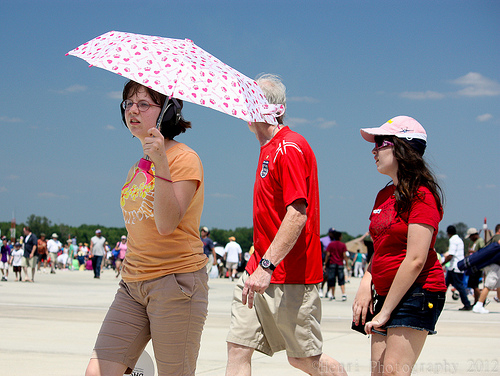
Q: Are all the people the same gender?
A: No, they are both male and female.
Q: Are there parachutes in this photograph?
A: No, there are no parachutes.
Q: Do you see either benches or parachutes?
A: No, there are no parachutes or benches.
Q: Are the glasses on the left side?
A: Yes, the glasses are on the left of the image.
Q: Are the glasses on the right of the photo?
A: No, the glasses are on the left of the image.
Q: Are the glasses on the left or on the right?
A: The glasses are on the left of the image.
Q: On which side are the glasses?
A: The glasses are on the left of the image.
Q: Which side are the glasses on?
A: The glasses are on the left of the image.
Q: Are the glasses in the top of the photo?
A: Yes, the glasses are in the top of the image.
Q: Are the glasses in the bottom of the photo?
A: No, the glasses are in the top of the image.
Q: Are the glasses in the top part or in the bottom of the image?
A: The glasses are in the top of the image.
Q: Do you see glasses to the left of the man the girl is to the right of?
A: Yes, there are glasses to the left of the man.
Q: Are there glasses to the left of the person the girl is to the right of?
A: Yes, there are glasses to the left of the man.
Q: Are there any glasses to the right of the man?
A: No, the glasses are to the left of the man.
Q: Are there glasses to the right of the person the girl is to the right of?
A: No, the glasses are to the left of the man.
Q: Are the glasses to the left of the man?
A: Yes, the glasses are to the left of the man.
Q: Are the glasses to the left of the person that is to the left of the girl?
A: Yes, the glasses are to the left of the man.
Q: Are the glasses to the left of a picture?
A: No, the glasses are to the left of the man.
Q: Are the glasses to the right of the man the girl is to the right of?
A: No, the glasses are to the left of the man.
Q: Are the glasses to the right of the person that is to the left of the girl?
A: No, the glasses are to the left of the man.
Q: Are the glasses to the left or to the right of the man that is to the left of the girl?
A: The glasses are to the left of the man.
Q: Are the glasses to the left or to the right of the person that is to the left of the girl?
A: The glasses are to the left of the man.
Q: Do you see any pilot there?
A: No, there are no pilots.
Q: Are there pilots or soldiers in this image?
A: No, there are no pilots or soldiers.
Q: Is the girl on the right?
A: Yes, the girl is on the right of the image.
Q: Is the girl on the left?
A: No, the girl is on the right of the image.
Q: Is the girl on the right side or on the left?
A: The girl is on the right of the image.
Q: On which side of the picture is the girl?
A: The girl is on the right of the image.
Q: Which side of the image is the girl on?
A: The girl is on the right of the image.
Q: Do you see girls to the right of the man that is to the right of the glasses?
A: Yes, there is a girl to the right of the man.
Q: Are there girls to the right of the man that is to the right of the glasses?
A: Yes, there is a girl to the right of the man.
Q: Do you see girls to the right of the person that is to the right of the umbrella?
A: Yes, there is a girl to the right of the man.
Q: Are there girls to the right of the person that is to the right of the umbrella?
A: Yes, there is a girl to the right of the man.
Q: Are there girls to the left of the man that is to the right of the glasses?
A: No, the girl is to the right of the man.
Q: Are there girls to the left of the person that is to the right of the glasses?
A: No, the girl is to the right of the man.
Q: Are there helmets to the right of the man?
A: No, there is a girl to the right of the man.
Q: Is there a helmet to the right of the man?
A: No, there is a girl to the right of the man.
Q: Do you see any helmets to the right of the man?
A: No, there is a girl to the right of the man.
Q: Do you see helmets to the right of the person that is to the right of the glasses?
A: No, there is a girl to the right of the man.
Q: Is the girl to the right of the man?
A: Yes, the girl is to the right of the man.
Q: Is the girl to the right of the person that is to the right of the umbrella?
A: Yes, the girl is to the right of the man.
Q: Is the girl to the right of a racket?
A: No, the girl is to the right of the man.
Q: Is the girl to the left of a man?
A: No, the girl is to the right of a man.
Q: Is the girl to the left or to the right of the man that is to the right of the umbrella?
A: The girl is to the right of the man.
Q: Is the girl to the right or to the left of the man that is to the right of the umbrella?
A: The girl is to the right of the man.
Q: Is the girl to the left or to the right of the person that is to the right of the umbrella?
A: The girl is to the right of the man.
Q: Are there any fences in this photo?
A: No, there are no fences.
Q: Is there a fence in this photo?
A: No, there are no fences.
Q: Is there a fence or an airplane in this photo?
A: No, there are no fences or airplanes.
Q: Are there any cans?
A: No, there are no cans.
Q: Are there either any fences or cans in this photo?
A: No, there are no cans or fences.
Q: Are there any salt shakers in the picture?
A: No, there are no salt shakers.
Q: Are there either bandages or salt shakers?
A: No, there are no salt shakers or bandages.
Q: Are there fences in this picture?
A: No, there are no fences.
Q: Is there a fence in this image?
A: No, there are no fences.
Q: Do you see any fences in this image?
A: No, there are no fences.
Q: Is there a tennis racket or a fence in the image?
A: No, there are no fences or rackets.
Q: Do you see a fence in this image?
A: No, there are no fences.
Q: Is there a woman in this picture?
A: Yes, there is a woman.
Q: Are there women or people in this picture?
A: Yes, there is a woman.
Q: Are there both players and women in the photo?
A: No, there is a woman but no players.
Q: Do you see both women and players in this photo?
A: No, there is a woman but no players.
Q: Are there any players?
A: No, there are no players.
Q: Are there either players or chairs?
A: No, there are no players or chairs.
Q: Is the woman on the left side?
A: Yes, the woman is on the left of the image.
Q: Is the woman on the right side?
A: No, the woman is on the left of the image.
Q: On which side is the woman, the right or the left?
A: The woman is on the left of the image.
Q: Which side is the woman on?
A: The woman is on the left of the image.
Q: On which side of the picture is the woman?
A: The woman is on the left of the image.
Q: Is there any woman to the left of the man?
A: Yes, there is a woman to the left of the man.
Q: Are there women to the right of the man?
A: No, the woman is to the left of the man.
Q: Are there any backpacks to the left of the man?
A: No, there is a woman to the left of the man.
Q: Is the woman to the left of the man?
A: Yes, the woman is to the left of the man.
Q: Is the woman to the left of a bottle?
A: No, the woman is to the left of the man.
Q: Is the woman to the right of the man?
A: No, the woman is to the left of the man.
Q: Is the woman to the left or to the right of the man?
A: The woman is to the left of the man.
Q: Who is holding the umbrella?
A: The woman is holding the umbrella.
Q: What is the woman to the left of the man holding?
A: The woman is holding the umbrella.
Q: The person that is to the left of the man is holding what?
A: The woman is holding the umbrella.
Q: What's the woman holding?
A: The woman is holding the umbrella.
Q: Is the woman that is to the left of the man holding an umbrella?
A: Yes, the woman is holding an umbrella.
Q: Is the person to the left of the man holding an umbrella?
A: Yes, the woman is holding an umbrella.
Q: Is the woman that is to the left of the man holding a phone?
A: No, the woman is holding an umbrella.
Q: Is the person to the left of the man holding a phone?
A: No, the woman is holding an umbrella.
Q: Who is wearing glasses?
A: The woman is wearing glasses.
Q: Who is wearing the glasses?
A: The woman is wearing glasses.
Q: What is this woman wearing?
A: The woman is wearing glasses.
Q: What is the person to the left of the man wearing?
A: The woman is wearing glasses.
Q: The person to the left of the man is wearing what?
A: The woman is wearing glasses.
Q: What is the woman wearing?
A: The woman is wearing glasses.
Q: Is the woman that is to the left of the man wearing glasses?
A: Yes, the woman is wearing glasses.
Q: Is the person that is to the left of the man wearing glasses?
A: Yes, the woman is wearing glasses.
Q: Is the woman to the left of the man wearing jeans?
A: No, the woman is wearing glasses.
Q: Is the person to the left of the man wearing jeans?
A: No, the woman is wearing glasses.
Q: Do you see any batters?
A: No, there are no batters.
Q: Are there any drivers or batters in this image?
A: No, there are no batters or drivers.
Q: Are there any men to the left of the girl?
A: Yes, there is a man to the left of the girl.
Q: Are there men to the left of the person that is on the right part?
A: Yes, there is a man to the left of the girl.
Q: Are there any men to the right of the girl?
A: No, the man is to the left of the girl.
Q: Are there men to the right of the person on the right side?
A: No, the man is to the left of the girl.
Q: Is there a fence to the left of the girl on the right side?
A: No, there is a man to the left of the girl.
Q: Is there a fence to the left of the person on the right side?
A: No, there is a man to the left of the girl.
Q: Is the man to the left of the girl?
A: Yes, the man is to the left of the girl.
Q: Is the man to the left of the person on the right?
A: Yes, the man is to the left of the girl.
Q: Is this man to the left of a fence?
A: No, the man is to the left of the girl.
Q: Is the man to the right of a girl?
A: No, the man is to the left of a girl.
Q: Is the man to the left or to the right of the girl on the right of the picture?
A: The man is to the left of the girl.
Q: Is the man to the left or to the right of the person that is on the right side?
A: The man is to the left of the girl.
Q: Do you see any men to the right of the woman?
A: Yes, there is a man to the right of the woman.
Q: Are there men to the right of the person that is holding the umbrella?
A: Yes, there is a man to the right of the woman.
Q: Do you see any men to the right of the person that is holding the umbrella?
A: Yes, there is a man to the right of the woman.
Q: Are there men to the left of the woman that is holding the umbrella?
A: No, the man is to the right of the woman.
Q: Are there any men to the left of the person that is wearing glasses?
A: No, the man is to the right of the woman.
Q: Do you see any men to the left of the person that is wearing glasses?
A: No, the man is to the right of the woman.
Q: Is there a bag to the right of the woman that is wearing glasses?
A: No, there is a man to the right of the woman.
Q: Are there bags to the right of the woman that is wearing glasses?
A: No, there is a man to the right of the woman.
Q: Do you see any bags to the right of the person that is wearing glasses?
A: No, there is a man to the right of the woman.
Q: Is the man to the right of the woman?
A: Yes, the man is to the right of the woman.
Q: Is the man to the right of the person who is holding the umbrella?
A: Yes, the man is to the right of the woman.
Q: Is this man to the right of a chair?
A: No, the man is to the right of the woman.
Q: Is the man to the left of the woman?
A: No, the man is to the right of the woman.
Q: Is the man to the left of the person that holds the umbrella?
A: No, the man is to the right of the woman.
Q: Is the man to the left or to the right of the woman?
A: The man is to the right of the woman.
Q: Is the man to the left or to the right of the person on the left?
A: The man is to the right of the woman.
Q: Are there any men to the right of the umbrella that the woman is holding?
A: Yes, there is a man to the right of the umbrella.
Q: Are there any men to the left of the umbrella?
A: No, the man is to the right of the umbrella.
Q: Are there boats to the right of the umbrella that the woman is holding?
A: No, there is a man to the right of the umbrella.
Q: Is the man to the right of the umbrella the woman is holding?
A: Yes, the man is to the right of the umbrella.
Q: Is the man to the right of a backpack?
A: No, the man is to the right of the umbrella.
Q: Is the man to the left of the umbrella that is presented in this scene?
A: No, the man is to the right of the umbrella.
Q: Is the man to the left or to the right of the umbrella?
A: The man is to the right of the umbrella.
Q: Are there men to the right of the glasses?
A: Yes, there is a man to the right of the glasses.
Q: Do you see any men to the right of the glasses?
A: Yes, there is a man to the right of the glasses.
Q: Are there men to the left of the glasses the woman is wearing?
A: No, the man is to the right of the glasses.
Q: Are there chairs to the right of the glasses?
A: No, there is a man to the right of the glasses.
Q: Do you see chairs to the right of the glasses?
A: No, there is a man to the right of the glasses.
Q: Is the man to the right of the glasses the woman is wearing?
A: Yes, the man is to the right of the glasses.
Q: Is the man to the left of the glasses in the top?
A: No, the man is to the right of the glasses.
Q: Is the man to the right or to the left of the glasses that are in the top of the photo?
A: The man is to the right of the glasses.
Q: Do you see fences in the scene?
A: No, there are no fences.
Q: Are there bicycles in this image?
A: No, there are no bicycles.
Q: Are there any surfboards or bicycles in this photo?
A: No, there are no bicycles or surfboards.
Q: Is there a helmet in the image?
A: No, there are no helmets.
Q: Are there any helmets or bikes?
A: No, there are no helmets or bikes.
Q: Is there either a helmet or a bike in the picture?
A: No, there are no helmets or bikes.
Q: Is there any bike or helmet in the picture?
A: No, there are no helmets or bikes.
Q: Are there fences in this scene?
A: No, there are no fences.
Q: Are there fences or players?
A: No, there are no fences or players.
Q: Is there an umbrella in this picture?
A: Yes, there is an umbrella.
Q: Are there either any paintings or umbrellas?
A: Yes, there is an umbrella.